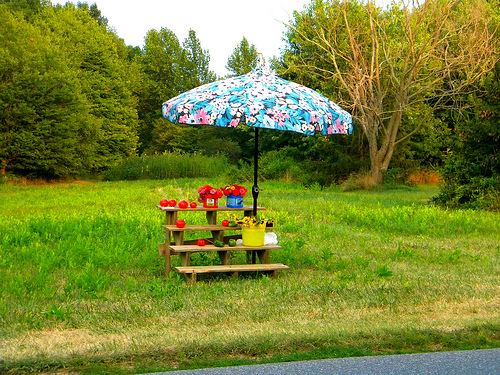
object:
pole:
[252, 127, 259, 265]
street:
[111, 351, 499, 375]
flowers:
[226, 212, 276, 228]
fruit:
[197, 239, 205, 246]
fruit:
[222, 220, 228, 226]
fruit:
[176, 219, 185, 228]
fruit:
[178, 200, 188, 209]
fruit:
[160, 199, 168, 207]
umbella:
[162, 52, 354, 136]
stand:
[158, 206, 290, 284]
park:
[0, 0, 500, 375]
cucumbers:
[213, 239, 236, 247]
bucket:
[243, 227, 265, 246]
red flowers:
[198, 184, 223, 203]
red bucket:
[203, 197, 218, 208]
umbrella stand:
[162, 54, 354, 265]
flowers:
[198, 184, 248, 203]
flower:
[220, 184, 247, 197]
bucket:
[227, 193, 244, 208]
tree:
[271, 0, 496, 190]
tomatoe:
[170, 215, 185, 227]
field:
[0, 166, 500, 375]